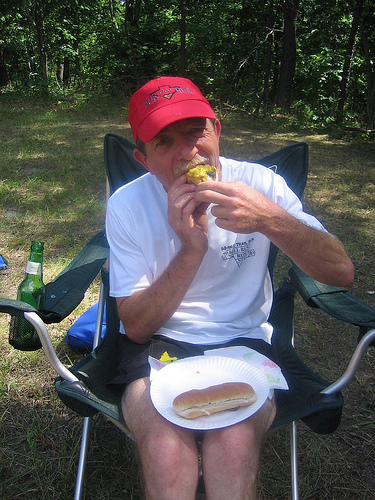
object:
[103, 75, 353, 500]
man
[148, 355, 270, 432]
paper plate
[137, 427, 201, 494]
lap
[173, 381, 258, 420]
hot dog bun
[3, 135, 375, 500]
chair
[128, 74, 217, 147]
cap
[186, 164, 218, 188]
food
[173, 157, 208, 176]
mustache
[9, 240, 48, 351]
beer bottle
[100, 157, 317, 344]
shirt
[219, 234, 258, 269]
emblem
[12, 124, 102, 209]
green grass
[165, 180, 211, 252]
hands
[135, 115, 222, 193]
face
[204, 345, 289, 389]
napkin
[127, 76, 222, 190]
head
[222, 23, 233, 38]
leaves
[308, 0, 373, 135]
trees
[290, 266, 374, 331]
arm rest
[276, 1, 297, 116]
tree trunk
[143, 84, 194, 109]
logo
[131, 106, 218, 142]
brim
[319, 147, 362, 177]
grass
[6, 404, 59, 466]
sparse grass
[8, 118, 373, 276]
ground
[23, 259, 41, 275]
label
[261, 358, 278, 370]
flower design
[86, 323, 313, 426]
sitting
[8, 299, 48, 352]
cup holder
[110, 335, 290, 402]
shorts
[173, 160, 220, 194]
eating